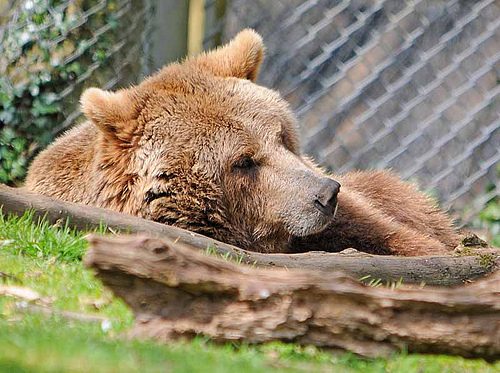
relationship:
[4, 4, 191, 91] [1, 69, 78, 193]
fence in bush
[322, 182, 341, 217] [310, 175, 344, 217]
part of nose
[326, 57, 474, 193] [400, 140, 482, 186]
part of mesh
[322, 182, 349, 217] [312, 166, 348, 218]
part of nose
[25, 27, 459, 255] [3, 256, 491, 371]
bear laying on ground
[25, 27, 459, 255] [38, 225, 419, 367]
bear laying on ground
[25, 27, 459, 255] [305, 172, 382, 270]
bear with nose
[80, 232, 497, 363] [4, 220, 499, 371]
log laying on ground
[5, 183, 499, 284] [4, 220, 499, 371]
branch laying on ground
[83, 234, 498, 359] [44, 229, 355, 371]
wood on ground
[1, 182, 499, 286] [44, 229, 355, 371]
wood on ground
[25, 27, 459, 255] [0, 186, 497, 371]
bear resting on ground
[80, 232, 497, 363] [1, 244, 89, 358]
log on ground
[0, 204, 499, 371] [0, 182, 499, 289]
grass under log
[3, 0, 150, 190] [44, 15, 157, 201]
bush behind fence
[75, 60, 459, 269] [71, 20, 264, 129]
bear has ears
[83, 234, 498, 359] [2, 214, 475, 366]
wood in grass